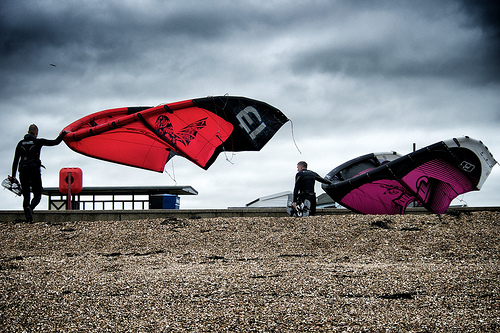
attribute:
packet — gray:
[2, 176, 24, 197]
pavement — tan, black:
[1, 209, 494, 221]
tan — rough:
[1, 209, 493, 215]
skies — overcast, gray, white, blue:
[0, 1, 500, 206]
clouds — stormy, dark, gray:
[1, 3, 499, 204]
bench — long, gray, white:
[41, 185, 200, 209]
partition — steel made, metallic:
[79, 196, 149, 208]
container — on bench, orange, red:
[62, 170, 83, 196]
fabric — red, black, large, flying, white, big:
[60, 93, 292, 174]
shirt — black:
[16, 138, 64, 172]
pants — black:
[19, 172, 41, 223]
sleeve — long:
[43, 136, 64, 144]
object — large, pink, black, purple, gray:
[322, 136, 497, 216]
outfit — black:
[296, 170, 331, 210]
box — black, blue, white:
[152, 194, 181, 211]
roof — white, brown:
[258, 189, 331, 199]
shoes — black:
[20, 206, 35, 226]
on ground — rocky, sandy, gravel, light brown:
[2, 207, 500, 332]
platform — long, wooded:
[0, 210, 500, 217]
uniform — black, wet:
[11, 134, 60, 216]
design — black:
[234, 106, 270, 151]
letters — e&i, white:
[238, 104, 264, 137]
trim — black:
[326, 151, 377, 188]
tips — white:
[448, 134, 499, 168]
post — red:
[67, 172, 73, 210]